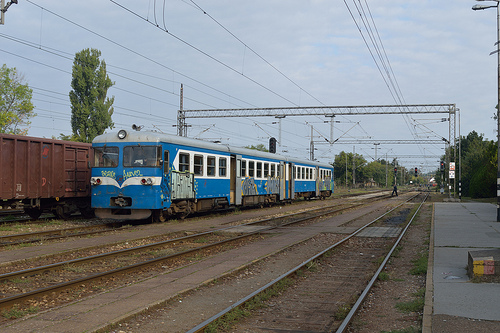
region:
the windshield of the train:
[86, 136, 168, 173]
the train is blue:
[81, 120, 347, 230]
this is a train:
[82, 123, 342, 228]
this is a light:
[116, 128, 131, 140]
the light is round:
[111, 123, 128, 143]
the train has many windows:
[170, 148, 334, 188]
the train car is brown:
[0, 128, 101, 222]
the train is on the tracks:
[3, 183, 427, 331]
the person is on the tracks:
[386, 175, 403, 195]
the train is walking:
[386, 174, 403, 199]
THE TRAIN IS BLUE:
[86, 123, 336, 218]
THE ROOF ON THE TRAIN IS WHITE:
[76, 121, 336, 168]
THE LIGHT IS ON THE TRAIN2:
[109, 125, 133, 139]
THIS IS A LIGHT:
[114, 128, 134, 141]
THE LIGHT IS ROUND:
[112, 122, 135, 142]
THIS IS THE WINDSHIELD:
[91, 141, 167, 167]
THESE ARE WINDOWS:
[175, 148, 336, 189]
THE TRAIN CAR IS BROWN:
[1, 128, 98, 229]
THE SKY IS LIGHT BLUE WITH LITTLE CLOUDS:
[4, 1, 499, 175]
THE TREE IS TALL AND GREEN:
[66, 45, 126, 147]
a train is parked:
[69, 135, 356, 207]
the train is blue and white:
[65, 127, 364, 217]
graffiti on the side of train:
[238, 173, 295, 198]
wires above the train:
[60, 12, 417, 94]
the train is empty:
[77, 126, 361, 230]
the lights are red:
[370, 159, 427, 186]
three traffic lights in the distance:
[360, 140, 450, 187]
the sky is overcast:
[95, 0, 445, 148]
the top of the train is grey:
[102, 122, 391, 166]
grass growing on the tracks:
[211, 257, 381, 329]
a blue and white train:
[88, 125, 341, 212]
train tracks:
[98, 175, 445, 330]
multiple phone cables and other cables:
[6, 0, 428, 142]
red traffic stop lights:
[392, 155, 449, 185]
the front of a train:
[88, 126, 173, 224]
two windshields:
[88, 140, 159, 171]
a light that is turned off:
[115, 127, 127, 142]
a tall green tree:
[59, 43, 122, 140]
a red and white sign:
[446, 160, 457, 179]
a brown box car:
[0, 129, 97, 214]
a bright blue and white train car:
[87, 131, 232, 225]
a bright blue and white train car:
[227, 140, 292, 210]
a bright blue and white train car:
[289, 155, 318, 197]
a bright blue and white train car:
[316, 161, 336, 193]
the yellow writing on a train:
[97, 165, 145, 182]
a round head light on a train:
[115, 129, 127, 139]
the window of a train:
[92, 143, 119, 167]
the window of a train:
[122, 145, 159, 166]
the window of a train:
[178, 148, 189, 176]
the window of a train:
[195, 152, 203, 177]